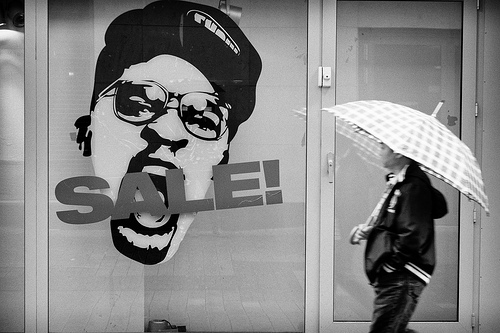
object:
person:
[350, 141, 450, 333]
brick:
[51, 235, 305, 333]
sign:
[56, 0, 284, 268]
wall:
[1, 2, 314, 333]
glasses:
[96, 80, 232, 141]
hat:
[91, 0, 263, 142]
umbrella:
[321, 99, 490, 217]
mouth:
[127, 159, 186, 228]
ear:
[74, 114, 92, 156]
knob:
[326, 151, 335, 183]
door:
[324, 1, 481, 333]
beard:
[110, 218, 179, 266]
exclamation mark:
[262, 159, 285, 205]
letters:
[54, 160, 263, 225]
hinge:
[475, 103, 478, 117]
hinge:
[477, 0, 480, 7]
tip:
[430, 100, 446, 118]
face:
[379, 144, 397, 168]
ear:
[395, 154, 402, 158]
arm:
[387, 183, 428, 260]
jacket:
[362, 164, 448, 286]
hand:
[353, 225, 374, 243]